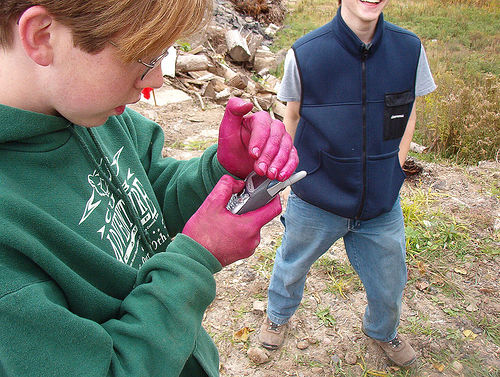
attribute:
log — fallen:
[223, 26, 250, 61]